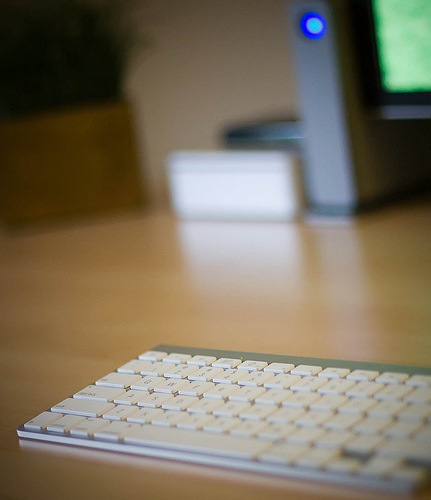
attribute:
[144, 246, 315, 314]
table — brown, wooden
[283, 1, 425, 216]
computer tower — blurry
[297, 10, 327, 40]
light — blue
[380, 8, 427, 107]
screen — green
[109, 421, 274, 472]
spacebar — white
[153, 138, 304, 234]
square — white, blurry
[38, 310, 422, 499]
keyboard — silver, white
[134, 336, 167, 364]
key — escape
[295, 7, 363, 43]
light — blue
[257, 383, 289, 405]
key — bright white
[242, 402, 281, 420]
key — bright white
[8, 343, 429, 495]
keyboard — white